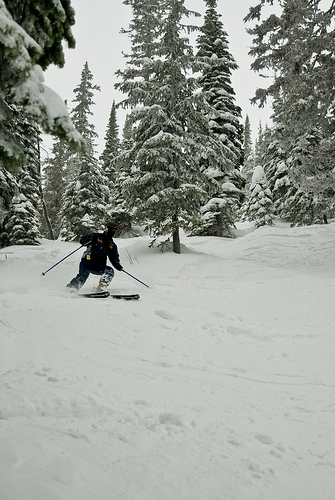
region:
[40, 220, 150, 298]
a person skiing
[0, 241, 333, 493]
a ski slope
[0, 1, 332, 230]
several large pine trees covered in snow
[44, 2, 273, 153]
a gray overcast and cloudy sky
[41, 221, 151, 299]
a man with a black jacket skiing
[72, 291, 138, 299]
snow skis in the snow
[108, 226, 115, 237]
black goggles and ski mask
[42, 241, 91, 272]
a ski pole in the skier's right hand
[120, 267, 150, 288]
a ski pole in the skier's left hand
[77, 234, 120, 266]
The skier's black ski jacket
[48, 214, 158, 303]
skier in the snow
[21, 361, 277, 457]
snow in the ground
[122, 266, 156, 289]
left ski pole on man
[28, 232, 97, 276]
ski pole held by man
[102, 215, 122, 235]
head of man skiing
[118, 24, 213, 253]
very tall pine tree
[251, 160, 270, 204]
tree with snow on the top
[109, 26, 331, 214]
trees on the ground in winter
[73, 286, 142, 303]
skis on a man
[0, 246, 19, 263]
bench covered in the snow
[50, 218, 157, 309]
a man on skiis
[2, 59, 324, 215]
trees covered with snow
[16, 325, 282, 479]
white snow on the ground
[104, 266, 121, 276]
left knee of person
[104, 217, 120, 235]
head of a skiier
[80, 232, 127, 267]
jacket of a man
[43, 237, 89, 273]
ski pole held in right hand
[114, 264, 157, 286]
ski pole held in left hand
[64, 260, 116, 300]
legs of a person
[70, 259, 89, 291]
right leg of person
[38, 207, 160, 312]
A man skiing wearing a black jacket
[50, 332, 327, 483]
A white snowy ski slope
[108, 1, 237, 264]
A snow covered pine tree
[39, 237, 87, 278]
A blue ski pole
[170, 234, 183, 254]
A brown pine tree trunk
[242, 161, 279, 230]
A small snow covered pine tree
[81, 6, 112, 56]
A gray cloudy sky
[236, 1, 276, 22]
A snow covered pine tree branch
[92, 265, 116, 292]
A man's snow covered left leg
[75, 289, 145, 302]
A pair of black skis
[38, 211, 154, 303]
skier going down mountain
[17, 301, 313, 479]
tracks in deep snow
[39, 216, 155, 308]
skier using blue ski poles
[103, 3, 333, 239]
pine trees covered in snow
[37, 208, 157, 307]
person wearing blue ski suit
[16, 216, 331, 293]
snow drifts under trees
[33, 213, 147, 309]
skier wearing face mask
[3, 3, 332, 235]
forest of snowy trees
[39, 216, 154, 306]
skier rushing down snow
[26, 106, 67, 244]
dead tree in snow